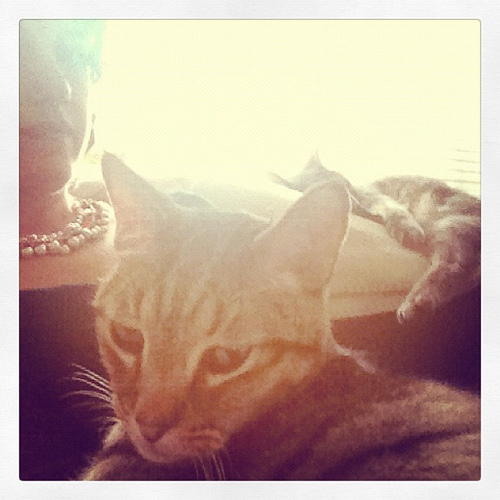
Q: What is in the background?
A: Light.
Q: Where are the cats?
A: In a room.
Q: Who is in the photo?
A: A lady and cats.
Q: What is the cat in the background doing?
A: Laying down.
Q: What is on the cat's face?
A: Whiskers.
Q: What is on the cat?
A: Stripes.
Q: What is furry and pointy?
A: Cats ear.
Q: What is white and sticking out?
A: Whiskers.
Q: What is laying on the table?
A: Cat.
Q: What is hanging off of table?
A: Cat's legs.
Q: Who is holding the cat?
A: A lady.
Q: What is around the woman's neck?
A: Pearls.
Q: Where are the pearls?
A: On necklace.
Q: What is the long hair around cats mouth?
A: Whiskers.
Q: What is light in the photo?
A: The window.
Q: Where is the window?
A: Next to the cat.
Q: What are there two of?
A: Cats.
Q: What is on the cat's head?
A: Ears.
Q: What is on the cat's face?
A: White whiskers.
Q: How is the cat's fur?
A: Striped.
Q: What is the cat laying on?
A: A pillow.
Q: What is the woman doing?
A: Looking at the cat.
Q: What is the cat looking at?
A: The camera.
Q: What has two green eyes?
A: The cat.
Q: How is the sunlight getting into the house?
A: Through the window.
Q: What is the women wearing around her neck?
A: A pearl necklace.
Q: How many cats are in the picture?
A: Two.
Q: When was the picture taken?
A: During the day.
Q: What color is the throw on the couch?
A: White.